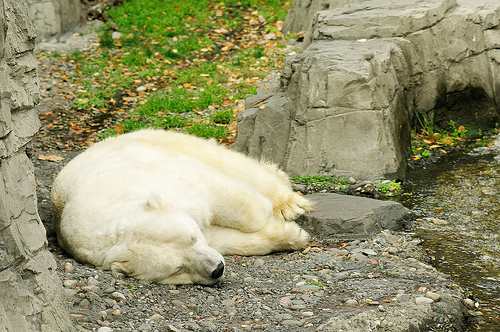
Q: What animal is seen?
A: Bear.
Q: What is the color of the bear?
A: White.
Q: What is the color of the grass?
A: Green.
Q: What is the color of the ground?
A: Grey.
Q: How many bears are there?
A: 1.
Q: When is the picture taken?
A: Daytime.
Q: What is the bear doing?
A: Sleeping.